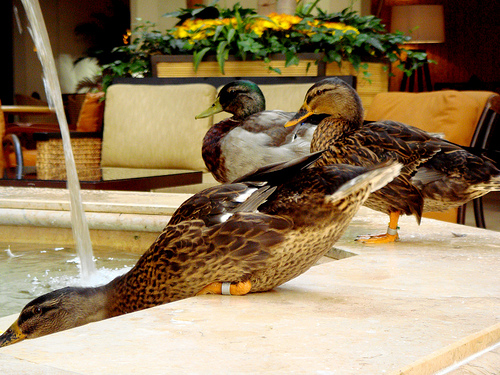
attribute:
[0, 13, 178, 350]
fountain — white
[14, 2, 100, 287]
fountain — white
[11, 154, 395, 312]
duck — brown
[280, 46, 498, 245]
duck — brown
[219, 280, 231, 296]
rubber band — white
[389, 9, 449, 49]
shade — brown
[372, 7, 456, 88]
lamp — white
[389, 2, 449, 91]
lamp — beige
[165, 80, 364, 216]
duck — brown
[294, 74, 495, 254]
duck — brown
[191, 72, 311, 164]
duck — brown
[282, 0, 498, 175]
duck — male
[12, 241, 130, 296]
water — clean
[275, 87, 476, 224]
duck — brown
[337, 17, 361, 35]
flower — yellow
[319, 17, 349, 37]
flower — yellow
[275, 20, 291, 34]
flower — yellow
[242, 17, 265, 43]
flower — yellow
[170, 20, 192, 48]
flower — yellow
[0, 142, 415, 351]
duck — brown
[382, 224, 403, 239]
strap — white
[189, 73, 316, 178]
duck — green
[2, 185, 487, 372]
pond — filled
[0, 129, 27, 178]
stand — steel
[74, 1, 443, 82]
greenery — long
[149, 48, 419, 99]
planter — wooden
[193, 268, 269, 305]
leg — orange